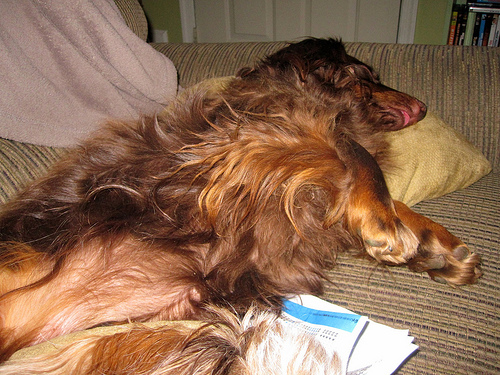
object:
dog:
[10, 22, 489, 370]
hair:
[247, 77, 291, 114]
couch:
[409, 56, 469, 90]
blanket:
[64, 37, 121, 80]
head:
[262, 25, 432, 141]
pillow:
[405, 139, 452, 184]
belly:
[120, 273, 204, 301]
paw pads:
[421, 251, 444, 271]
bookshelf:
[445, 1, 499, 52]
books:
[456, 12, 470, 41]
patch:
[226, 106, 271, 144]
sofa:
[168, 46, 225, 68]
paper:
[287, 301, 419, 373]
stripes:
[8, 146, 30, 170]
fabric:
[129, 9, 142, 22]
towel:
[16, 10, 120, 113]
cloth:
[13, 40, 44, 86]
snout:
[408, 91, 430, 130]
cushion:
[426, 125, 458, 146]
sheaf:
[244, 308, 272, 327]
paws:
[379, 242, 442, 269]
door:
[181, 3, 401, 38]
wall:
[154, 4, 182, 23]